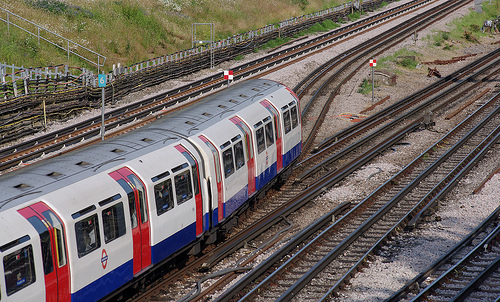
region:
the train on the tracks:
[0, 64, 325, 297]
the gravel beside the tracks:
[373, 221, 458, 278]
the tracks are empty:
[210, 130, 498, 300]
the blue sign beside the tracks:
[82, 73, 123, 124]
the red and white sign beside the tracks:
[358, 55, 395, 72]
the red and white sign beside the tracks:
[214, 62, 241, 77]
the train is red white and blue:
[6, 75, 311, 300]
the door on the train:
[22, 203, 89, 300]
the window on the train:
[66, 196, 135, 245]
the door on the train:
[97, 165, 176, 269]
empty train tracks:
[394, 94, 495, 284]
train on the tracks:
[9, 96, 302, 267]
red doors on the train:
[111, 163, 168, 283]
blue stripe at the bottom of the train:
[141, 219, 272, 274]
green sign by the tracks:
[85, 66, 114, 136]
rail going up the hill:
[11, 8, 107, 67]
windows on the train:
[71, 208, 133, 245]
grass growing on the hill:
[85, 17, 158, 52]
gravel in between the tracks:
[368, 159, 387, 194]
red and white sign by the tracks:
[363, 52, 384, 97]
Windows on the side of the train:
[72, 193, 138, 250]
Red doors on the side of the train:
[112, 158, 159, 275]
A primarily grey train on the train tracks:
[3, 72, 318, 289]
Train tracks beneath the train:
[277, 158, 333, 213]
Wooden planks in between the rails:
[284, 255, 335, 295]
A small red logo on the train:
[97, 247, 117, 271]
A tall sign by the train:
[94, 66, 113, 144]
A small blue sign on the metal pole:
[96, 70, 112, 90]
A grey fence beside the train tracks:
[4, 6, 114, 68]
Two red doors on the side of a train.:
[165, 125, 229, 240]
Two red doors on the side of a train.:
[17, 146, 41, 299]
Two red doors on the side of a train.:
[160, 227, 427, 261]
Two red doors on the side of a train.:
[212, 134, 240, 274]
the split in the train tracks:
[299, 65, 345, 182]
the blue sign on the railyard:
[94, 71, 108, 89]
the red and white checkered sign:
[365, 54, 378, 69]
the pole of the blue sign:
[100, 87, 105, 139]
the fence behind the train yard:
[1, 67, 93, 124]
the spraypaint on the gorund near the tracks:
[336, 108, 366, 123]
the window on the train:
[222, 128, 247, 182]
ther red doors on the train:
[14, 200, 74, 300]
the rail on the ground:
[468, 158, 498, 204]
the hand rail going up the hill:
[1, 1, 108, 76]